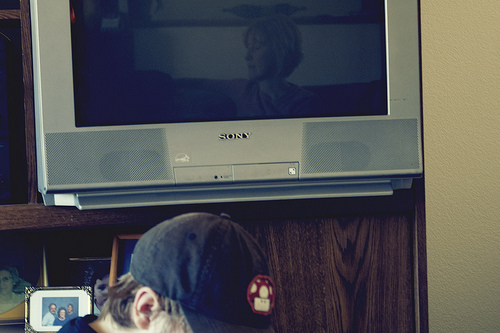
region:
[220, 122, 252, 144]
the TV is a sony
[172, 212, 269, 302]
he is wearing a hat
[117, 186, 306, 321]
the hat is black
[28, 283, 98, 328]
family picture behind him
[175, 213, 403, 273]
the entertainment center is wooden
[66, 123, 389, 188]
the TV has two speakers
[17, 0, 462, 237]
this is a television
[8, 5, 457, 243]
the television is grey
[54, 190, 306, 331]
this is a person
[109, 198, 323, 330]
this is a hat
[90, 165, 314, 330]
person wearing a hat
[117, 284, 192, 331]
this is an ear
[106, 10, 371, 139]
reflection on the television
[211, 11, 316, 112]
woman has head turned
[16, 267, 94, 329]
this is a picture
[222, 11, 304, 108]
reflection of a woman in on the TV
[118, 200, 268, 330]
man wearing a black hat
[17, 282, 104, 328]
picture of a family on the shelf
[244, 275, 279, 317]
logo on a hat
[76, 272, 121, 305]
picture of a baby on the shelf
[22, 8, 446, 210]
TV in a book case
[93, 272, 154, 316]
person with blonde hair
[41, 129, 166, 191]
speaker on a television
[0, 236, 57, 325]
Picture of a lady on a shelf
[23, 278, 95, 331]
picture of a family on the shelf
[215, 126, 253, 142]
brand name of an old TV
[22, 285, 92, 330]
framed photo of a family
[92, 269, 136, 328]
shaggy hair protruding from a cap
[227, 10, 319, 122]
reflection of a woman in the TV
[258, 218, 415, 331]
wood grain in the shelving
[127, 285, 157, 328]
right ear of the man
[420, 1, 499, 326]
beige wall on the right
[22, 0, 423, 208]
old fashioned TV set on a shelf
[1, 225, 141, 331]
a group of framed photos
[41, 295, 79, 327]
the photo of the family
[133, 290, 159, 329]
the ear of the man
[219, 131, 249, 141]
the trademark Sony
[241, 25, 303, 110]
a woman on the TVdisplay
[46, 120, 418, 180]
the speakers of the TV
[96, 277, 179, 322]
the hair of mman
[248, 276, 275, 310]
a figure on the cap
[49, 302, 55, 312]
the head of man